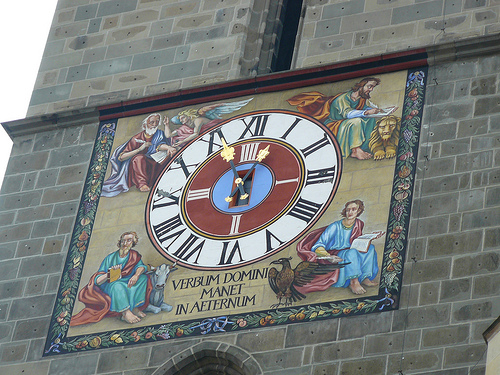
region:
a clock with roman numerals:
[143, 110, 348, 277]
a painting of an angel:
[166, 107, 263, 130]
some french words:
[166, 270, 299, 316]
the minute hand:
[211, 127, 257, 213]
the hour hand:
[213, 127, 281, 212]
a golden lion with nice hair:
[366, 113, 403, 163]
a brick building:
[28, 17, 482, 350]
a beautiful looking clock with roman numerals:
[65, 80, 443, 350]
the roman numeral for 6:
[216, 237, 248, 274]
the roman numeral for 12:
[237, 112, 279, 142]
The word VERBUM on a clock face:
[170, 274, 225, 289]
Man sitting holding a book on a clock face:
[81, 232, 161, 323]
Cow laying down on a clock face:
[146, 256, 178, 310]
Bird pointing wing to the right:
[263, 252, 350, 302]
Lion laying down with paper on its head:
[366, 107, 404, 162]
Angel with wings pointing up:
[158, 95, 274, 146]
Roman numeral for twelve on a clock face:
[237, 112, 274, 140]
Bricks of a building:
[7, 177, 64, 305]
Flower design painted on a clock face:
[235, 300, 352, 328]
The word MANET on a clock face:
[197, 278, 252, 299]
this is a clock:
[191, 124, 316, 254]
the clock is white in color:
[193, 131, 298, 226]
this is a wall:
[423, 212, 485, 332]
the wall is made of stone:
[427, 181, 495, 312]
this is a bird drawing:
[273, 255, 303, 299]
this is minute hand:
[221, 143, 240, 176]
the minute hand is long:
[218, 142, 242, 170]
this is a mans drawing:
[320, 203, 380, 302]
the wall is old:
[434, 142, 491, 288]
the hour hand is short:
[251, 142, 278, 179]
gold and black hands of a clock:
[216, 133, 272, 208]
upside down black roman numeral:
[218, 236, 245, 267]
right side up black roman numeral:
[236, 114, 271, 139]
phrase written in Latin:
[171, 262, 278, 314]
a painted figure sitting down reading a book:
[295, 191, 386, 301]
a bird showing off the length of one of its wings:
[261, 248, 353, 306]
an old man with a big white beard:
[114, 114, 179, 194]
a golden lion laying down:
[368, 111, 403, 161]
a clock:
[146, 106, 351, 276]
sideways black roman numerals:
[301, 164, 338, 188]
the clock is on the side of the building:
[120, 107, 342, 275]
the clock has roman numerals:
[132, 109, 343, 269]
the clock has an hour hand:
[219, 145, 305, 205]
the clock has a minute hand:
[200, 136, 253, 200]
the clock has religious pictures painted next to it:
[97, 59, 409, 320]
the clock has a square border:
[66, 65, 432, 370]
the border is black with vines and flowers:
[36, 72, 430, 356]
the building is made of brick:
[13, 37, 104, 353]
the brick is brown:
[0, 93, 87, 322]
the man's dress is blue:
[312, 217, 379, 294]